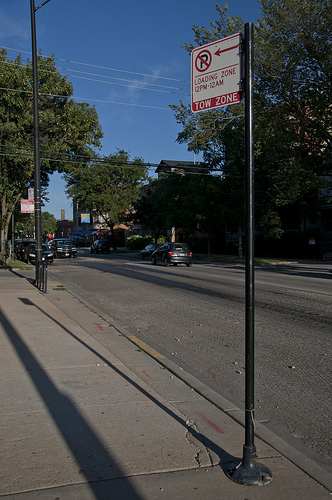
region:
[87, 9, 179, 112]
this is the sky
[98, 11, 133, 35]
the sky is blue in color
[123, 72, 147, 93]
these are the clouds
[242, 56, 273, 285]
this is a pole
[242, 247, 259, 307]
the pole is black in color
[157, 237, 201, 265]
this is a car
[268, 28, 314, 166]
this is a tree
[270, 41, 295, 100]
the leaves are green in color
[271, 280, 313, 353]
this is the road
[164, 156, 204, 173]
this is a building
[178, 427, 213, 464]
cracks in the sidewalk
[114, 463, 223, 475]
long line in the sidewalk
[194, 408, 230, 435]
red paint on the sidewalk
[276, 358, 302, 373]
small stone in the street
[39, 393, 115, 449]
pole's shadow on the sidewalk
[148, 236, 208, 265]
small car driving on the street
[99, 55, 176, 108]
small puff of white cloud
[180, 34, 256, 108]
red and white direction sign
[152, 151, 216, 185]
sloped roof on building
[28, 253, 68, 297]
black barrier on street corner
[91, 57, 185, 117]
A white cloud in the sky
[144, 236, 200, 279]
A car on the road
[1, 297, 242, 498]
Shadows on the sidewalk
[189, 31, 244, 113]
Red and white street sign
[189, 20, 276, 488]
Black post holding up the sign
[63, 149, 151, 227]
Green leaves on a tree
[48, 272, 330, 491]
The curb of a sidewalk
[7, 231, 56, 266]
Cars parked on side of the road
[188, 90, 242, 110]
The words "TOW ZONE" on sign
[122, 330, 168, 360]
Part of the curb painted yellow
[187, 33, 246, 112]
it is a red and white sign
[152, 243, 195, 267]
it is a dark blue car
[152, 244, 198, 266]
it is a dark blue car in the street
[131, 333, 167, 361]
it is yellow writing on the curb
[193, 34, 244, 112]
it is a no parking sign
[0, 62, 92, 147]
big tall trees in the background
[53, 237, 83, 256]
it is a black truck in the street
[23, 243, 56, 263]
it is a black car parked in the street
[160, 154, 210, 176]
the top of a building in the background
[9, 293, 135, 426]
shadows on the sidewalk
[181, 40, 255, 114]
The sign warns of a tow zone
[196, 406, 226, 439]
A small marking of red paint on the ground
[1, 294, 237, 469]
A long black shadow of the pole on the ground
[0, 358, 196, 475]
Grey concrete tiles on the sidewalk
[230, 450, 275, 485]
The circular metal base of the pole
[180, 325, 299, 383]
Small rocks littering the clean road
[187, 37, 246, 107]
A square white sign on the pole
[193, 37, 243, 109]
A red trima round the square white sign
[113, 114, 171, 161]
An open blue sky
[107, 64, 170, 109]
A wispy white cloud in the sky